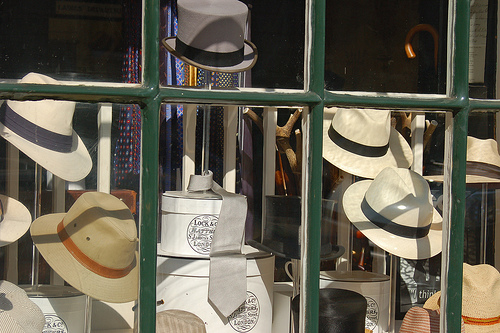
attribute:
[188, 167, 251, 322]
tie — grey, wrapped, neck , white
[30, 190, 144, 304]
hat — tan, brown, shadowy, photographed, rimmed, sided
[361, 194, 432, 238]
band — black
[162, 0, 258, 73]
hat — white, tophat, grey, black, gray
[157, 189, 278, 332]
boxes — stacked, small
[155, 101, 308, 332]
window — glass, green, paneled, trimmed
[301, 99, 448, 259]
hats — beige, similar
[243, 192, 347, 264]
hat — black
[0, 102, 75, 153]
strip — black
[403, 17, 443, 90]
stick — walking, wooden, brown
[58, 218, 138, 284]
strap — brown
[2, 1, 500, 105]
background — dark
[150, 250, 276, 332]
box — large